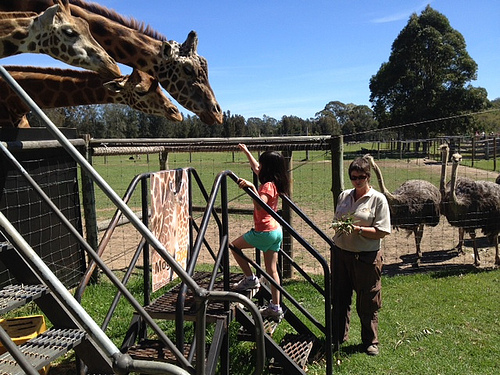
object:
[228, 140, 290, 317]
girl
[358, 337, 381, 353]
shoe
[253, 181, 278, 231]
shirt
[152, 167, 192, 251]
image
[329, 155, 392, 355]
person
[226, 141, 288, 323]
person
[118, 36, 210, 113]
giraffe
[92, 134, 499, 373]
grassy terrain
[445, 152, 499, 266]
bird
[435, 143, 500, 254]
bird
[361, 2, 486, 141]
tree background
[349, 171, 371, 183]
sunglasses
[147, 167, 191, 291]
sign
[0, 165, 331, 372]
gate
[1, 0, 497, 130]
sky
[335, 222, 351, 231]
leaves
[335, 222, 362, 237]
hand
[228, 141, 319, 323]
girl stairs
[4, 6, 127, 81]
giraffe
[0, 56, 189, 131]
giraffe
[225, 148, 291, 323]
woman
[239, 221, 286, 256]
shorts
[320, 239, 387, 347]
pants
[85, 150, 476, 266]
fence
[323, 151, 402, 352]
woman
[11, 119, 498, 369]
pen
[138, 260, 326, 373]
stairs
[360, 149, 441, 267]
bird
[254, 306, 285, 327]
shoe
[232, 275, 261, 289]
shoe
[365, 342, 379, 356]
foot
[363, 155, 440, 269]
ostrich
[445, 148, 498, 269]
ostrich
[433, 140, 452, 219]
ostrich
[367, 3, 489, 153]
tree